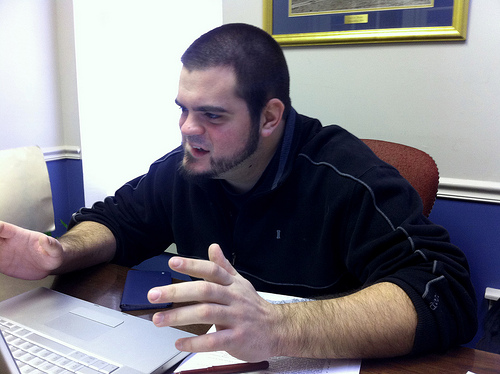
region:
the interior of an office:
[0, 0, 499, 373]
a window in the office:
[71, 0, 222, 255]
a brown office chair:
[359, 137, 439, 217]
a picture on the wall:
[261, 0, 471, 47]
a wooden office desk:
[0, 251, 498, 372]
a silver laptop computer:
[0, 284, 200, 372]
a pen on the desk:
[170, 359, 268, 372]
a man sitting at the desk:
[0, 23, 479, 362]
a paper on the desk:
[172, 290, 361, 372]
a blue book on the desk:
[119, 268, 171, 310]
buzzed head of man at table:
[158, 17, 302, 184]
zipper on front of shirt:
[272, 220, 292, 240]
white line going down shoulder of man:
[310, 148, 385, 215]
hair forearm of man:
[275, 285, 392, 345]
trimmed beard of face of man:
[224, 112, 259, 169]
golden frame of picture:
[352, 28, 458, 43]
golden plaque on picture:
[332, 11, 374, 27]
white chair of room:
[0, 145, 51, 235]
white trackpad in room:
[51, 305, 116, 342]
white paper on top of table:
[195, 288, 337, 372]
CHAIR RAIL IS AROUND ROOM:
[435, 177, 499, 197]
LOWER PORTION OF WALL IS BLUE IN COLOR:
[442, 207, 497, 319]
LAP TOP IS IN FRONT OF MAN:
[0, 283, 204, 371]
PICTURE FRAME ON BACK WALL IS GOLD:
[261, 3, 473, 50]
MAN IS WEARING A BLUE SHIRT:
[89, 124, 474, 345]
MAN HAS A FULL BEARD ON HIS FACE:
[168, 116, 275, 185]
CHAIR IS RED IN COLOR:
[336, 115, 454, 236]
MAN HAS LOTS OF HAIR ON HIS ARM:
[239, 292, 421, 366]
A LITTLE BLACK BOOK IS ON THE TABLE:
[113, 258, 170, 321]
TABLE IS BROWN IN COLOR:
[71, 260, 140, 315]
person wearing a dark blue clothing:
[2, 27, 490, 366]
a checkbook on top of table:
[114, 259, 179, 314]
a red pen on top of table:
[160, 360, 277, 372]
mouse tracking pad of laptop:
[33, 287, 133, 347]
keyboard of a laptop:
[0, 251, 206, 371]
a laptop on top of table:
[0, 275, 206, 370]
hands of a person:
[147, 238, 287, 363]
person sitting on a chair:
[7, 19, 484, 366]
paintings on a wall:
[254, 0, 471, 49]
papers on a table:
[164, 272, 386, 372]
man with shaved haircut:
[142, 13, 337, 191]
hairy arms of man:
[141, 238, 454, 372]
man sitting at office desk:
[1, 18, 477, 370]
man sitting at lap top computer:
[3, 31, 457, 366]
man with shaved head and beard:
[156, 11, 297, 191]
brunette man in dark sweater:
[56, 19, 455, 338]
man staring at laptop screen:
[3, 11, 448, 363]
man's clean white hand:
[142, 233, 273, 368]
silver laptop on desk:
[2, 261, 203, 372]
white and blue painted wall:
[445, 130, 485, 232]